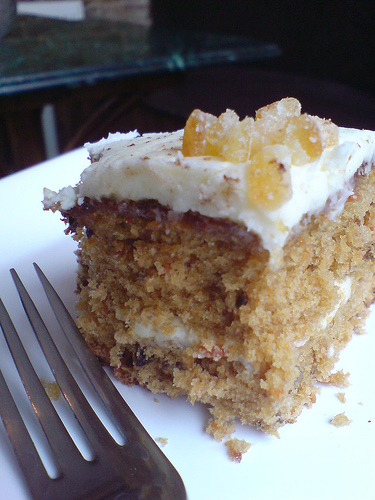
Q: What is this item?
A: A cake.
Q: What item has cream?
A: The cake.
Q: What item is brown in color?
A: The cake.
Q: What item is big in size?
A: The cake.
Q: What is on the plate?
A: A slice of cake.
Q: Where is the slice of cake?
A: On a plate.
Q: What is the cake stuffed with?
A: A layer of white cream.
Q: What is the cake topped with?
A: White cream and yellow dried fruit.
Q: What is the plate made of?
A: Porcelain.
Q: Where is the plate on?
A: On a dark table.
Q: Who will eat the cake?
A: The person who sliced it.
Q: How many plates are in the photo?
A: One.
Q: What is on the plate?
A: A piece of cake.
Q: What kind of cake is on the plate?
A: Pineapple.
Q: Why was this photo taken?
A: For a magazine.